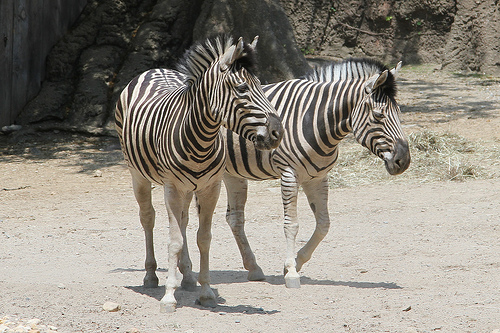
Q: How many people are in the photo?
A: None.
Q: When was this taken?
A: Daytime.